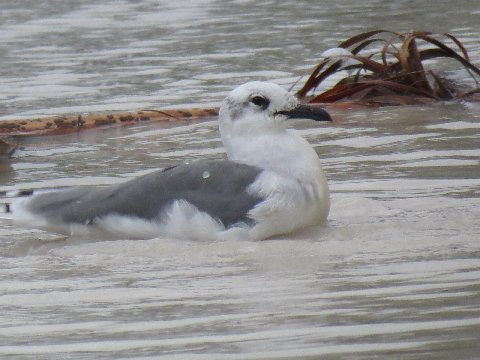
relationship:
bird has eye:
[8, 80, 333, 241] [246, 92, 274, 112]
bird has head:
[0, 84, 333, 238] [216, 80, 332, 134]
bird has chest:
[0, 84, 333, 238] [274, 130, 331, 195]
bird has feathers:
[8, 80, 333, 241] [2, 185, 77, 234]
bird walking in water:
[8, 80, 333, 241] [24, 235, 469, 351]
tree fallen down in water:
[1, 96, 223, 149] [0, 0, 478, 359]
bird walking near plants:
[0, 84, 333, 238] [292, 28, 480, 107]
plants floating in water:
[297, 28, 479, 104] [4, 253, 475, 359]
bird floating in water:
[8, 80, 333, 241] [0, 0, 478, 359]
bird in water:
[8, 80, 333, 241] [0, 0, 478, 359]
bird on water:
[8, 80, 333, 241] [0, 0, 478, 359]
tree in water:
[1, 103, 212, 139] [0, 0, 478, 359]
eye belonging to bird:
[250, 95, 266, 106] [0, 84, 333, 238]